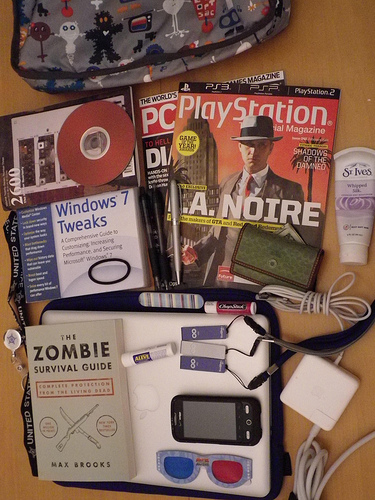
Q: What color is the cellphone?
A: Black.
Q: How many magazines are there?
A: 2.